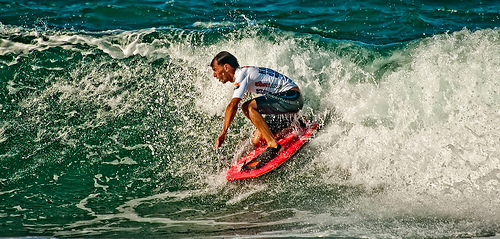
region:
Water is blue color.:
[16, 126, 87, 215]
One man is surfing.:
[203, 48, 317, 172]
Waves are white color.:
[308, 41, 468, 192]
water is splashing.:
[281, 44, 474, 196]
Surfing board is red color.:
[222, 118, 315, 186]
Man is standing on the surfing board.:
[218, 61, 313, 181]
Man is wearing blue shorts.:
[255, 93, 307, 120]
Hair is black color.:
[216, 51, 238, 63]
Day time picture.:
[18, 14, 478, 226]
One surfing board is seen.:
[227, 126, 304, 176]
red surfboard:
[208, 111, 345, 196]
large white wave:
[292, 28, 499, 215]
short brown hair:
[190, 41, 245, 86]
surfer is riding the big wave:
[194, 42, 347, 191]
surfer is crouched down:
[200, 48, 339, 190]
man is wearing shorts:
[241, 80, 328, 132]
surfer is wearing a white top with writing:
[208, 57, 306, 112]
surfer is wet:
[201, 53, 339, 188]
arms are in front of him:
[202, 74, 268, 157]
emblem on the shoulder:
[224, 73, 251, 100]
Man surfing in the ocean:
[207, 23, 349, 218]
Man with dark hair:
[194, 33, 250, 85]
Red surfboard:
[227, 84, 368, 196]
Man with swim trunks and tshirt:
[238, 55, 320, 137]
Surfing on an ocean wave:
[106, 61, 463, 228]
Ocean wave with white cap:
[360, 60, 498, 231]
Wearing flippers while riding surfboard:
[238, 132, 299, 188]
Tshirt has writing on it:
[242, 66, 313, 106]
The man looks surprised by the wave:
[201, 31, 337, 197]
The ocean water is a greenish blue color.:
[19, 12, 150, 236]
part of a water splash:
[361, 70, 429, 120]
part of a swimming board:
[241, 170, 269, 185]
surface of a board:
[258, 151, 273, 164]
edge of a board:
[216, 162, 248, 182]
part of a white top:
[244, 67, 281, 92]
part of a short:
[268, 103, 293, 113]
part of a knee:
[237, 98, 257, 121]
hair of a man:
[211, 41, 235, 61]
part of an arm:
[217, 102, 243, 144]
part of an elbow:
[221, 96, 241, 112]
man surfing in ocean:
[191, 48, 318, 188]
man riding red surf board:
[230, 125, 330, 190]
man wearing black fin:
[241, 141, 279, 175]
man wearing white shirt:
[231, 62, 296, 101]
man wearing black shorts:
[252, 82, 311, 117]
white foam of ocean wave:
[346, 67, 483, 187]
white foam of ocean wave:
[244, 29, 333, 70]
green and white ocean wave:
[280, 12, 487, 73]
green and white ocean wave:
[6, 10, 198, 230]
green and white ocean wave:
[127, 13, 416, 48]